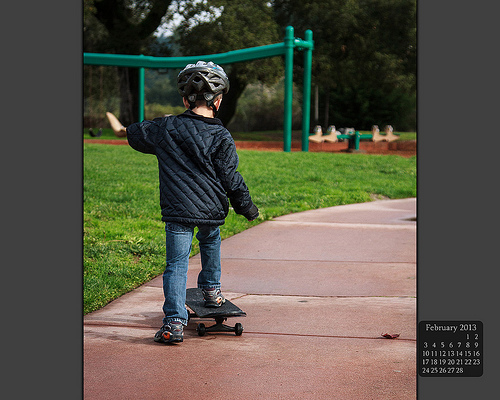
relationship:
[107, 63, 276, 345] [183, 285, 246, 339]
boy on skateboard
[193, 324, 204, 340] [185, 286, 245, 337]
wheel on skateboard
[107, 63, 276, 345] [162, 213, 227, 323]
boy wearing jeans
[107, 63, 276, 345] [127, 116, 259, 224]
boy wearing jacket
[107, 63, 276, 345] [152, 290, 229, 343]
boy wearing shoe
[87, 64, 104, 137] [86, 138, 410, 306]
swing by grass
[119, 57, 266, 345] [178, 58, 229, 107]
boy has helmet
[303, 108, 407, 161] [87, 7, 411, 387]
teeter totters at park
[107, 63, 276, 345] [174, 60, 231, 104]
boy wearing helmet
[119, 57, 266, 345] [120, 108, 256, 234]
boy wearing coat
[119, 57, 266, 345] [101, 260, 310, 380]
boy has shoe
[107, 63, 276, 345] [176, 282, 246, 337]
boy on skateboard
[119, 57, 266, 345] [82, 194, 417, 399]
boy skateboarding on sidewalk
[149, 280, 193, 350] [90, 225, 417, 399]
foot on sidewalk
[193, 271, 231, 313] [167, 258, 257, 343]
foot on skateboard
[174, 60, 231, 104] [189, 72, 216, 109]
helmet on head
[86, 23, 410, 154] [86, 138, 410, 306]
playground in grass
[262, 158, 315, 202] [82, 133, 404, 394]
grass on ground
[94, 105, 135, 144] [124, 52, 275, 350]
hand of rider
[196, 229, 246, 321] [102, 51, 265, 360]
leg of rider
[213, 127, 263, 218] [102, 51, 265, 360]
hand of rider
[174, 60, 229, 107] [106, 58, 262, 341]
helmet of rider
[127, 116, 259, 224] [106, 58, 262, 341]
jacket of rider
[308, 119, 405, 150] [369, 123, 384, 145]
see saw with seat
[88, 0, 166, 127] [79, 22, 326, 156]
tree behind swing set